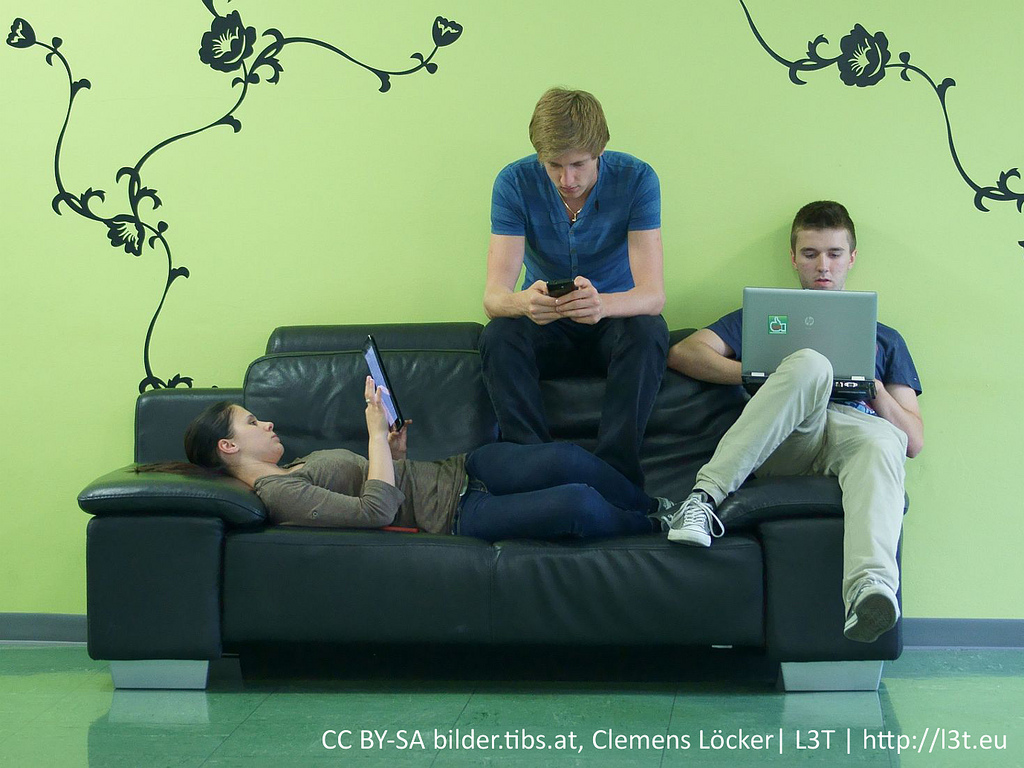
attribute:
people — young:
[187, 85, 922, 646]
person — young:
[473, 80, 689, 488]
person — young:
[665, 168, 916, 652]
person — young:
[172, 386, 694, 543]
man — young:
[653, 196, 917, 637]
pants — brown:
[677, 348, 906, 637]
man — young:
[476, 82, 663, 466]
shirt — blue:
[478, 149, 671, 298]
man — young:
[653, 184, 922, 671]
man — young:
[444, 88, 678, 465]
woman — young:
[181, 389, 682, 541]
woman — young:
[155, 369, 675, 541]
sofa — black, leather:
[73, 316, 912, 684]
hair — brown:
[529, 86, 607, 154]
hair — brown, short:
[782, 193, 853, 251]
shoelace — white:
[658, 489, 728, 532]